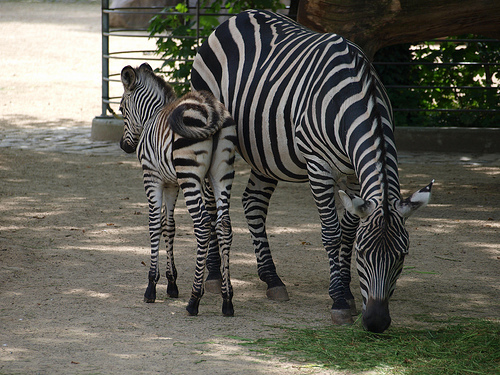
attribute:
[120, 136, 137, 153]
snout — black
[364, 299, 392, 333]
snout — black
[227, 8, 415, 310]
zebra — adult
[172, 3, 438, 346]
zebra — adult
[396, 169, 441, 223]
ear — long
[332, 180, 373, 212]
ear — long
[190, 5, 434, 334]
zebra — adult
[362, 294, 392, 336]
nose — black, white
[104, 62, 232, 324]
zebra — baby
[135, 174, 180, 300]
legs — skinny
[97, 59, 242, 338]
zebra — small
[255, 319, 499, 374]
grass — green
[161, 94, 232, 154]
tail — small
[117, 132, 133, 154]
snout — black 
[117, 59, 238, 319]
zebra — young, small, baby